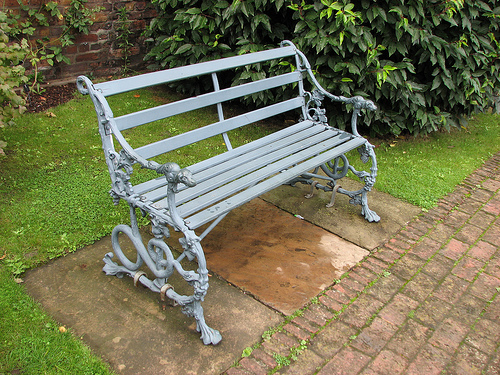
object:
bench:
[76, 38, 383, 346]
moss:
[235, 317, 304, 368]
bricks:
[225, 320, 498, 374]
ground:
[0, 165, 497, 375]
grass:
[0, 346, 105, 375]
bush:
[141, 0, 500, 129]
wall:
[0, 0, 154, 89]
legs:
[101, 220, 223, 344]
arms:
[76, 73, 194, 186]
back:
[95, 45, 303, 162]